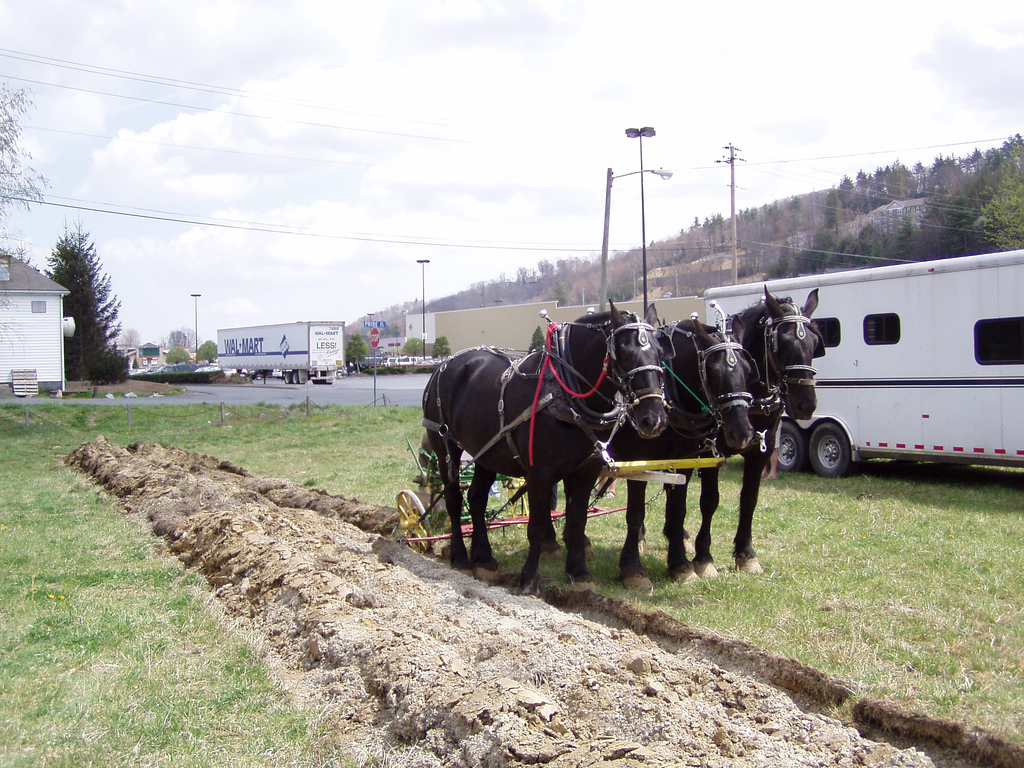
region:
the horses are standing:
[421, 277, 823, 597]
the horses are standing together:
[424, 287, 827, 597]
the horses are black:
[419, 280, 821, 588]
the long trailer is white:
[706, 244, 1021, 478]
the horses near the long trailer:
[424, 243, 1022, 601]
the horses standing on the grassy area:
[1, 284, 1020, 762]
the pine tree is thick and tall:
[48, 209, 131, 383]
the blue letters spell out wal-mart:
[213, 319, 347, 386]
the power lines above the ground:
[0, 41, 1021, 765]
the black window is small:
[861, 313, 900, 346]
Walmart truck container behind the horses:
[208, 322, 342, 379]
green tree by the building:
[40, 230, 126, 392]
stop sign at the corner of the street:
[362, 322, 385, 417]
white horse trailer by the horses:
[801, 256, 1021, 475]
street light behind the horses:
[612, 105, 676, 292]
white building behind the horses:
[11, 246, 79, 409]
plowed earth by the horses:
[93, 426, 641, 759]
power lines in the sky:
[22, 40, 228, 123]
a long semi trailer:
[213, 319, 347, 383]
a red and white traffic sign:
[364, 322, 383, 398]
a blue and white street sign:
[359, 317, 391, 331]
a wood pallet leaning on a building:
[10, 361, 39, 401]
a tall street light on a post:
[615, 115, 667, 299]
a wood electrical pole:
[722, 137, 741, 303]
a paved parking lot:
[248, 370, 417, 409]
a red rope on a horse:
[513, 317, 621, 453]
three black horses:
[411, 288, 836, 570]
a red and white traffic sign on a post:
[358, 332, 396, 400]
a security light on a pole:
[620, 111, 656, 323]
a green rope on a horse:
[651, 342, 713, 426]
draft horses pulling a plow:
[396, 282, 821, 609]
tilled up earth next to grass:
[65, 426, 1005, 766]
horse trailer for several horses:
[702, 246, 1022, 481]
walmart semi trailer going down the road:
[213, 315, 341, 383]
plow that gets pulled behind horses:
[387, 440, 544, 543]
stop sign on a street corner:
[362, 322, 386, 403]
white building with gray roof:
[0, 249, 84, 389]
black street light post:
[626, 119, 674, 309]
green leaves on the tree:
[915, 181, 974, 227]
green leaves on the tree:
[813, 209, 908, 238]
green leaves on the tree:
[748, 221, 788, 244]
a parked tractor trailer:
[212, 320, 348, 396]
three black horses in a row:
[408, 292, 819, 603]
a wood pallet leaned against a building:
[7, 364, 43, 399]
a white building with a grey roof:
[11, 240, 60, 381]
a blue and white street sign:
[359, 310, 388, 333]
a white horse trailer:
[700, 241, 1017, 486]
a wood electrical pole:
[719, 136, 754, 292]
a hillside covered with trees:
[678, 162, 992, 267]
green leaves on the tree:
[928, 177, 979, 225]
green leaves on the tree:
[966, 199, 1023, 234]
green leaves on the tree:
[976, 171, 1018, 219]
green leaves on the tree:
[103, 313, 133, 364]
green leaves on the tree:
[50, 303, 109, 370]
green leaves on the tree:
[54, 239, 128, 329]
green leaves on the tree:
[638, 217, 673, 252]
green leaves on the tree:
[432, 252, 489, 307]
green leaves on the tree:
[448, 247, 509, 299]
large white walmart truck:
[215, 316, 346, 383]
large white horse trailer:
[702, 243, 1020, 478]